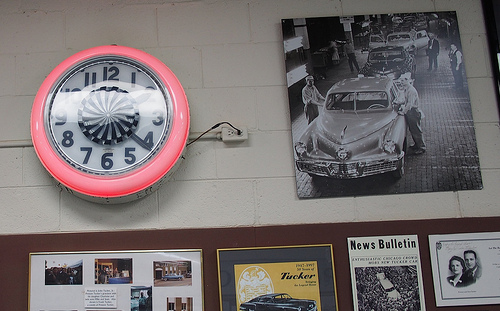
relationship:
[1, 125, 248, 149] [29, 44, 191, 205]
conduit behind clock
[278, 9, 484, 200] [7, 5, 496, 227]
poster on wall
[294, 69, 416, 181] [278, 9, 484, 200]
car on poster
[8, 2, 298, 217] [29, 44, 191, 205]
wall behind clock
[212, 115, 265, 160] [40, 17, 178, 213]
plug part of clock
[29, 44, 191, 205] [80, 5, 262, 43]
clock on wall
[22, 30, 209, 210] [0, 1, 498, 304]
clock on wall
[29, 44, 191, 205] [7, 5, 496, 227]
clock on wall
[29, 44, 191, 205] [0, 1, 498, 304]
clock on wall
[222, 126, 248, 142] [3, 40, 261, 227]
outlet next to clock